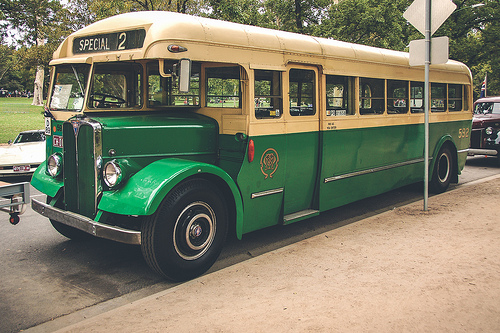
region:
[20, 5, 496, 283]
this is a bus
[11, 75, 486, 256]
green bottom of bus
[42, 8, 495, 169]
tan top of bus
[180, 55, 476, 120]
row of bus windows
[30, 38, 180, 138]
front windows on bus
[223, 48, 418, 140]
windows on the bus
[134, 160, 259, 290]
front tire of bus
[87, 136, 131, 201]
light on front of bus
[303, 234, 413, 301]
sidewalk next to bus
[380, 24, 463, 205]
pole next to bus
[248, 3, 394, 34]
trees in the distance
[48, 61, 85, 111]
glass window on bus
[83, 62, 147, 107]
glass window on bus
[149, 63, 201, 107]
glass window on bus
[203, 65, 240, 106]
glass window on bus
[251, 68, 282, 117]
glass window on bus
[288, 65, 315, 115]
glass window on bus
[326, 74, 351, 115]
glass window on bus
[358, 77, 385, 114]
glass window on bus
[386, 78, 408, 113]
glass window on bus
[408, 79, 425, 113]
glass window on bus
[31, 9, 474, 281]
a vintage green and tan bus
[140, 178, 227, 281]
a bus front tire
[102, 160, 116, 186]
a bus front headlight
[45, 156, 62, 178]
a bus front headlight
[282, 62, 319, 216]
a bus door entrance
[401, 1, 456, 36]
back of street traffic sign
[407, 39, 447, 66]
back of street traffic sign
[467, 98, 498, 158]
a parked vintage car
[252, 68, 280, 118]
a bus passenger window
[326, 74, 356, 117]
a bus passenger window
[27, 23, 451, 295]
this is a bus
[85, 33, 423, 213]
the bus is green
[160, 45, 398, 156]
the bus is white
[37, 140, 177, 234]
the bus has headlights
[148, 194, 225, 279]
the wheels are black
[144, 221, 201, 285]
the wheels are rubber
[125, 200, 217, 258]
this is a tire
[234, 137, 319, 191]
the logo is orange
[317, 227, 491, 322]
this is a bus stop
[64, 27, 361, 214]
this is a public bus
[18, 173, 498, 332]
sand covered street island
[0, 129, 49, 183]
white painted sports car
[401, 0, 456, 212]
two metal street signs on a pole seen from behind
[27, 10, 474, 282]
tan and green city bus